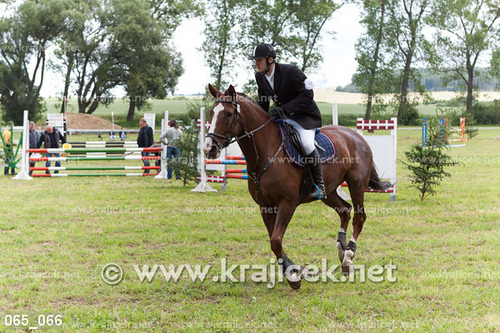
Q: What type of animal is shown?
A: Horse.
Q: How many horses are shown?
A: One.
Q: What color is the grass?
A: Green.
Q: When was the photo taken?
A: Daytime.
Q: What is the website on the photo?
A: www.krajicek.net.